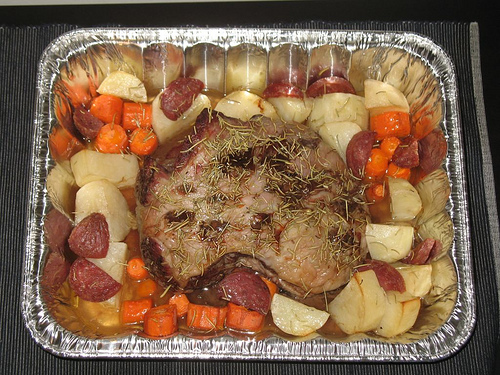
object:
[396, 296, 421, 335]
edge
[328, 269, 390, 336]
potato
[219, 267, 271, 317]
meat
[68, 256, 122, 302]
meat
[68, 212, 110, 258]
meat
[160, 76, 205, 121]
meat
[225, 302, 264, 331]
vegetable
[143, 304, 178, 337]
vegetable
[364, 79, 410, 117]
vegetable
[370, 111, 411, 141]
carrot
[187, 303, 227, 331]
carrot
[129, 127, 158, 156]
carrot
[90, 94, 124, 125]
carrot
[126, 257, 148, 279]
carrot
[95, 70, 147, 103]
veggies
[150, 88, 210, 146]
veggies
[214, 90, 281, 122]
veggies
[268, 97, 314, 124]
veggies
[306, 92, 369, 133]
veggies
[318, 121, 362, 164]
veggies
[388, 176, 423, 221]
veggies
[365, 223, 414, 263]
veggies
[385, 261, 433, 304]
veggies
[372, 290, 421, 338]
veggies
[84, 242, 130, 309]
veggies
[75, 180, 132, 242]
veggies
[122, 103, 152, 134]
veggies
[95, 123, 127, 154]
veggies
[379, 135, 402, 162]
veggies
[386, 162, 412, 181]
veggies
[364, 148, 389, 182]
veggies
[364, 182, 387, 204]
veggies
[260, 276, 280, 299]
veggies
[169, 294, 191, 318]
veggies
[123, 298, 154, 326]
veggies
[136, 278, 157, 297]
veggies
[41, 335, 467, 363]
creases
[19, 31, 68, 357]
creases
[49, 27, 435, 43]
creases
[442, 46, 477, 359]
creases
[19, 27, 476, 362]
container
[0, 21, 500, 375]
mat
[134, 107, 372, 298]
beef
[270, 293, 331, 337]
potato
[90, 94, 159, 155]
carrots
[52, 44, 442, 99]
foil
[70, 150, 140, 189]
sliced potato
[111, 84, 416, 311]
herbs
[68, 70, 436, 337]
food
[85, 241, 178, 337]
vegetables